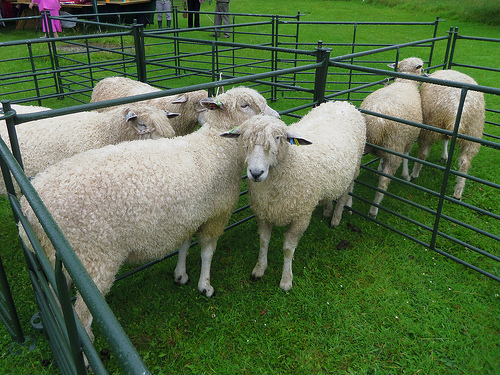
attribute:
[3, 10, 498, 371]
cage — green, mettalic, metal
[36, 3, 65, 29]
dress — pink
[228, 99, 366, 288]
sheep — big, white, standing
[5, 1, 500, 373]
grass — green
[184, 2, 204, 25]
pants — black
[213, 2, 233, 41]
pants — gray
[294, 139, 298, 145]
tag — green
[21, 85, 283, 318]
sheep — white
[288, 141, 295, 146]
tag — blue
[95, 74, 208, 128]
sheep — white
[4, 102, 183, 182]
sheep — white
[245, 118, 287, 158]
hair — hanging, long